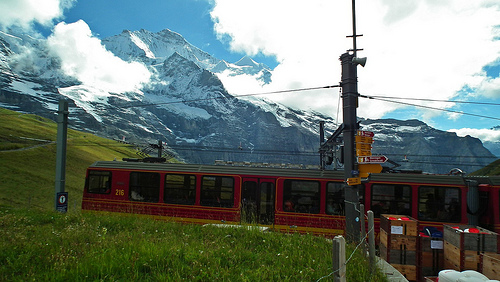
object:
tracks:
[64, 141, 320, 167]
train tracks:
[370, 152, 500, 168]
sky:
[383, 0, 499, 84]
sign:
[357, 130, 377, 137]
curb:
[362, 250, 407, 281]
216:
[113, 188, 125, 196]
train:
[80, 160, 500, 242]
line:
[68, 84, 340, 113]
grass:
[16, 207, 88, 278]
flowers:
[236, 235, 291, 259]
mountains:
[0, 11, 499, 174]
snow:
[57, 83, 134, 122]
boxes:
[417, 235, 445, 281]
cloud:
[206, 0, 498, 99]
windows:
[127, 170, 236, 209]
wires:
[0, 111, 59, 115]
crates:
[443, 224, 499, 279]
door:
[240, 176, 279, 223]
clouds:
[33, 19, 154, 123]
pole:
[339, 50, 359, 250]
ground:
[0, 107, 137, 203]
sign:
[356, 154, 390, 164]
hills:
[15, 97, 121, 203]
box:
[378, 213, 419, 280]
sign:
[56, 191, 70, 212]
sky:
[206, 0, 320, 52]